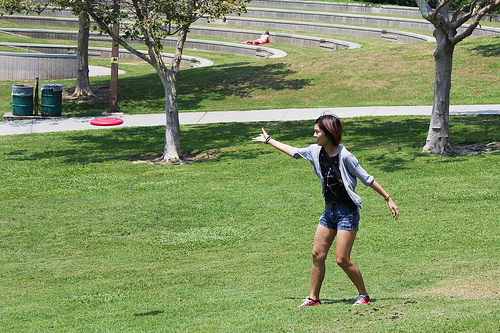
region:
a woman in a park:
[249, 114, 397, 308]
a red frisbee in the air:
[87, 115, 123, 125]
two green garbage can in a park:
[13, 81, 64, 116]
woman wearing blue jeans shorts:
[321, 203, 362, 228]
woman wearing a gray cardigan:
[293, 144, 373, 206]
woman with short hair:
[312, 113, 344, 150]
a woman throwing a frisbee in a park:
[91, 114, 400, 310]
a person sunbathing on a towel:
[246, 30, 273, 47]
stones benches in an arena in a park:
[0, 0, 499, 84]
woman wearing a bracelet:
[264, 134, 272, 144]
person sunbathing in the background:
[246, 30, 272, 45]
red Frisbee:
[89, 114, 124, 129]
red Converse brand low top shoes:
[293, 295, 373, 307]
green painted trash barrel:
[10, 82, 34, 115]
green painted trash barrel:
[40, 81, 64, 116]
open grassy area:
[1, 112, 498, 330]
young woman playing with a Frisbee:
[253, 110, 402, 308]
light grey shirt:
[291, 142, 374, 207]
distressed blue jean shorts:
[313, 205, 360, 231]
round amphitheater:
[1, 0, 498, 80]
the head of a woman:
[272, 79, 392, 171]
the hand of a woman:
[245, 105, 281, 155]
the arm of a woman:
[256, 114, 323, 191]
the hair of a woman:
[300, 73, 368, 177]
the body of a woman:
[294, 88, 391, 303]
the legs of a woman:
[296, 176, 381, 311]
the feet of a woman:
[283, 282, 411, 323]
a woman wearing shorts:
[298, 189, 385, 256]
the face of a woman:
[303, 113, 341, 153]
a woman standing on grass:
[274, 62, 403, 327]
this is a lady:
[256, 102, 410, 309]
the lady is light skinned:
[337, 237, 353, 255]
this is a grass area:
[118, 193, 203, 260]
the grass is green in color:
[147, 197, 219, 263]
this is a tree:
[92, 5, 162, 68]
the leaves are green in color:
[152, 1, 210, 11]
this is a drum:
[44, 76, 63, 120]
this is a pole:
[91, 47, 127, 112]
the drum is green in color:
[38, 92, 61, 120]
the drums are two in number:
[12, 77, 72, 114]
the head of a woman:
[310, 114, 342, 150]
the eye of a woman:
[300, 111, 334, 140]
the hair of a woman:
[313, 105, 359, 151]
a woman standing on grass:
[294, 98, 370, 315]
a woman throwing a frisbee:
[29, 57, 425, 182]